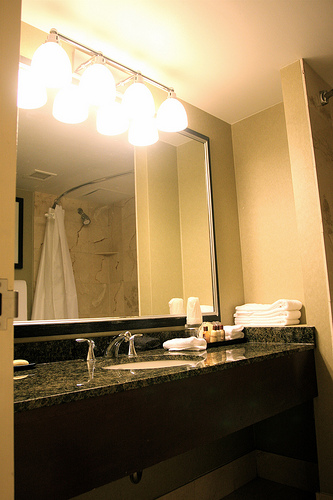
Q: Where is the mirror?
A: Above the sink.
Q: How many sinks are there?
A: One.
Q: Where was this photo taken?
A: In the bathroom.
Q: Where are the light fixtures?
A: Above the mirror.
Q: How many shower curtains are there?
A: One.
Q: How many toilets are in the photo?
A: Zero.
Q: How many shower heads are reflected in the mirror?
A: One.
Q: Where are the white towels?
A: Stacked on the countertop.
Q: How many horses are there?
A: None.